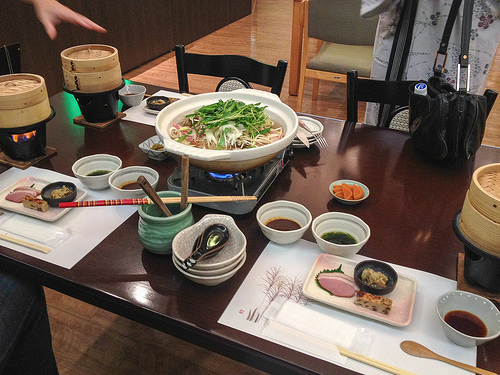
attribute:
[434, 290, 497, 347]
bowl — white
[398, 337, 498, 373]
spoon — brown, wood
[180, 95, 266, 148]
vegetables — green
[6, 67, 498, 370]
table — brown, dark, wooden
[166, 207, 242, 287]
dish — white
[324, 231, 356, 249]
sauce — green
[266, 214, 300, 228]
sauce — red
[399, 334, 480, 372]
spoon — wooden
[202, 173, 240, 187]
flame — blue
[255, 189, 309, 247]
bowl — white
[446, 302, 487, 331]
soup — brown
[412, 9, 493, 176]
purse — black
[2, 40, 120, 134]
bamboo boxes — wooden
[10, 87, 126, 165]
flame heaters — portable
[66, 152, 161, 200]
two dishes — at each setting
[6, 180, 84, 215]
items — to eat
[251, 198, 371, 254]
food bowls — little, white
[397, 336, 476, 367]
wooden spoon — one, long handled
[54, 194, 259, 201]
wooden chopsticks — long , resting on bowl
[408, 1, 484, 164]
black purse — one, long handled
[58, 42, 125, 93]
bamboo container — little, round, light colored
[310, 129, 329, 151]
fork tines — shiny, metal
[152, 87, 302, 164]
white dish — large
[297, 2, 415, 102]
cushioned chair — green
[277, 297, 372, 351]
white napkin — wrapped in plastic